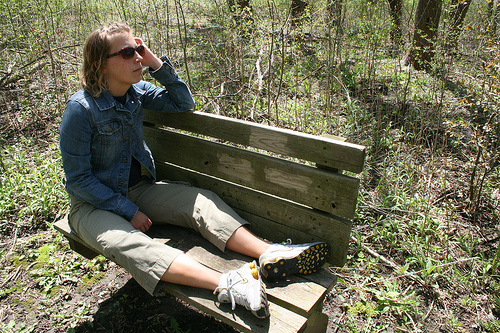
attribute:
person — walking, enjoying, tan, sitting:
[57, 21, 328, 318]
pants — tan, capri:
[68, 179, 250, 300]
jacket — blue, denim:
[57, 55, 194, 221]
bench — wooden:
[50, 106, 366, 332]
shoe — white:
[263, 241, 331, 285]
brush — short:
[0, 142, 67, 225]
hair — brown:
[84, 23, 130, 98]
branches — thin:
[250, 47, 266, 120]